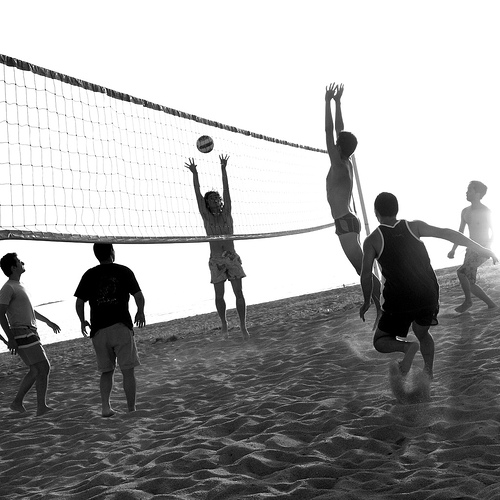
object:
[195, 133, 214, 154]
volleyball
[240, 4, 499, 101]
sky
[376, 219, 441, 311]
shirt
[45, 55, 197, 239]
net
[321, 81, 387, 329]
man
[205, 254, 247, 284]
swim trunks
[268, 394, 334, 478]
beach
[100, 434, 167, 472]
footprints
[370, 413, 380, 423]
shadow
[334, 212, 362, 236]
speedo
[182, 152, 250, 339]
men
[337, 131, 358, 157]
hair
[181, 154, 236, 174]
arms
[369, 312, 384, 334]
foot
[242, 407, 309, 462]
tracks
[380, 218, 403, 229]
tank top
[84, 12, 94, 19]
sun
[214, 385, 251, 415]
ripples